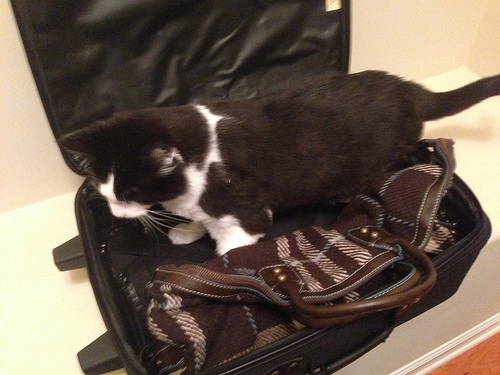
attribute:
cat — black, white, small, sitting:
[35, 27, 498, 260]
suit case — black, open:
[13, 0, 495, 375]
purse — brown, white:
[146, 190, 498, 347]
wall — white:
[1, 2, 500, 204]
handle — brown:
[272, 244, 446, 326]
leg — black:
[45, 226, 113, 274]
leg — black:
[76, 322, 133, 375]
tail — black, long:
[396, 66, 498, 115]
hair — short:
[88, 98, 432, 234]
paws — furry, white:
[164, 216, 250, 258]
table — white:
[5, 172, 495, 343]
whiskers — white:
[134, 202, 191, 239]